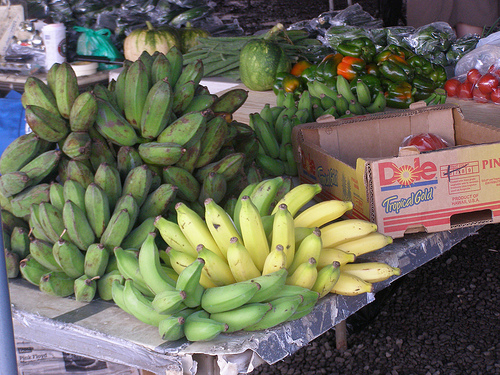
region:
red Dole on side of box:
[375, 150, 436, 193]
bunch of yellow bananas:
[152, 177, 400, 305]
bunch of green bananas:
[107, 225, 317, 347]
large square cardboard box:
[280, 85, 499, 250]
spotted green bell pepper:
[233, 25, 283, 106]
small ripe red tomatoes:
[437, 47, 499, 120]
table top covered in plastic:
[10, 201, 471, 373]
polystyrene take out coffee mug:
[32, 12, 74, 83]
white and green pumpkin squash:
[118, 12, 181, 75]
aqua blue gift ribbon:
[70, 20, 120, 67]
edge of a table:
[117, 327, 164, 354]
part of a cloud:
[374, 305, 428, 363]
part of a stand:
[325, 309, 352, 370]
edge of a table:
[101, 335, 123, 346]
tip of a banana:
[262, 295, 271, 315]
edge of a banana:
[218, 289, 242, 303]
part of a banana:
[336, 329, 354, 360]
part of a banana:
[223, 250, 248, 276]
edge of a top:
[267, 356, 290, 363]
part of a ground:
[398, 297, 451, 359]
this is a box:
[383, 158, 492, 201]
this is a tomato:
[481, 71, 491, 89]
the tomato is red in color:
[484, 72, 493, 86]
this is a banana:
[313, 202, 361, 244]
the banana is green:
[201, 278, 256, 310]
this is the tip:
[250, 280, 264, 291]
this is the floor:
[396, 305, 471, 373]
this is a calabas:
[129, 30, 159, 50]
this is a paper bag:
[86, 27, 113, 67]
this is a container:
[47, 19, 69, 49]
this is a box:
[313, 125, 498, 208]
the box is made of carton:
[345, 123, 371, 148]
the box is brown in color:
[346, 130, 379, 150]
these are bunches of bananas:
[43, 85, 260, 302]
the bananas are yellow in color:
[234, 215, 272, 246]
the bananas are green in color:
[87, 82, 163, 149]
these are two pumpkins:
[122, 22, 216, 59]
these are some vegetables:
[322, 46, 443, 96]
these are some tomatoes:
[453, 77, 496, 93]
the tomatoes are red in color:
[460, 78, 487, 100]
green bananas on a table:
[3, 36, 407, 339]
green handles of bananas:
[11, 37, 383, 187]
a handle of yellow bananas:
[162, 179, 407, 296]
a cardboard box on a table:
[262, 91, 497, 248]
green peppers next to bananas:
[271, 22, 451, 122]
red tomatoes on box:
[445, 59, 498, 109]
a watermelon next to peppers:
[234, 28, 285, 94]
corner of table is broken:
[133, 328, 291, 373]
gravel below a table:
[316, 277, 498, 373]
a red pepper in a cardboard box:
[331, 96, 498, 220]